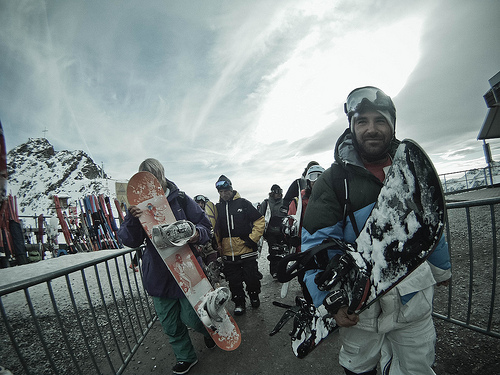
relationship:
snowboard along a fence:
[126, 171, 241, 352] [3, 245, 151, 374]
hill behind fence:
[6, 137, 130, 244] [3, 245, 151, 374]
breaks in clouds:
[201, 55, 234, 106] [247, 19, 343, 148]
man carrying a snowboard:
[287, 80, 456, 374] [291, 138, 447, 355]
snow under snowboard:
[360, 237, 391, 276] [291, 138, 447, 355]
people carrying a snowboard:
[118, 158, 217, 375] [128, 168, 244, 353]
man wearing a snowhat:
[287, 80, 456, 374] [345, 81, 398, 136]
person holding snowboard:
[287, 80, 456, 374] [291, 138, 447, 355]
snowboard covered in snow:
[291, 138, 447, 355] [360, 237, 391, 276]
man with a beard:
[287, 80, 456, 374] [355, 130, 393, 153]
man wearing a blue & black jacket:
[287, 80, 456, 374] [306, 150, 457, 294]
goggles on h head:
[339, 84, 395, 114] [331, 82, 403, 159]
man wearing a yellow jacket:
[203, 166, 272, 287] [206, 200, 268, 259]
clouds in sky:
[247, 19, 343, 148] [221, 46, 329, 128]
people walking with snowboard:
[128, 80, 446, 375] [126, 171, 241, 352]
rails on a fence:
[63, 279, 131, 351] [3, 245, 151, 374]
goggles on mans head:
[339, 84, 395, 114] [331, 82, 403, 159]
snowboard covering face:
[128, 168, 244, 353] [154, 172, 165, 186]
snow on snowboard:
[360, 237, 391, 276] [291, 138, 447, 355]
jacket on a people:
[116, 178, 214, 298] [118, 158, 217, 375]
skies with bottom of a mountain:
[9, 71, 269, 136] [20, 208, 58, 225]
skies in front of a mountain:
[9, 71, 269, 136] [20, 208, 58, 225]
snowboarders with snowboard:
[128, 80, 446, 375] [126, 171, 241, 352]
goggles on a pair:
[339, 84, 395, 114] [354, 94, 370, 101]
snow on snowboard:
[360, 237, 391, 276] [291, 138, 447, 359]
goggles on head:
[339, 84, 395, 114] [331, 82, 403, 159]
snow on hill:
[35, 165, 46, 178] [21, 147, 72, 197]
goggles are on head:
[339, 84, 395, 114] [331, 82, 403, 159]